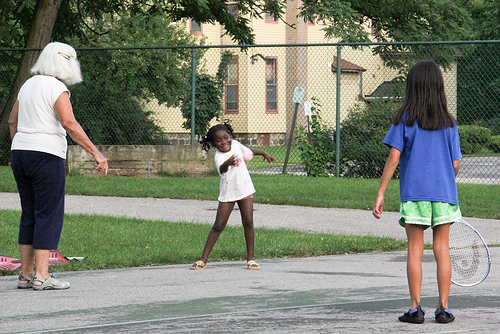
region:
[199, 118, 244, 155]
the head of the girl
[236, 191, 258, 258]
the leg of the girl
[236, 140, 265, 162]
the arm of the girl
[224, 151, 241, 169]
the hand of the girl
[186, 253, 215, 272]
the foot of the girl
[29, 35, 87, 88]
the head of the woman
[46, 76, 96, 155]
the arm of the woman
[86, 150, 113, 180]
the hand of the woman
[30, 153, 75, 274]
the leg of the woman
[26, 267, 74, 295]
the foot of the woman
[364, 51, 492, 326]
The closest girl has a tennis racket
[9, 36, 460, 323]
There are three people in the shot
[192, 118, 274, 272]
The middle girl has on a white shirt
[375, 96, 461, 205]
The girl on right has on a blue shirt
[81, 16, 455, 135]
The house is a light orange color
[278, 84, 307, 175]
The sign and post are bent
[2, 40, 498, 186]
The fence is chain link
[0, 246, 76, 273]
There is pink sports equipment in the grass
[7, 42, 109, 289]
The woman on left is elderly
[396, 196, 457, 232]
Person on right is wearing green shorts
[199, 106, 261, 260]
girl is playing on sidewalk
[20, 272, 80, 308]
lady has on grey shoes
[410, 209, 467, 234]
girl is wearing green shorts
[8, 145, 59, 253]
woman has black pants on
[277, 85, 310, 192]
the sign is crooked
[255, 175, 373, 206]
the grass behind the girl is green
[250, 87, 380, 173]
there is a fence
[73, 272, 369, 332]
sidewalk is gray in color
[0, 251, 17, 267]
pink equipment on ground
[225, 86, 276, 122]
building has two windows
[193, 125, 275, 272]
Girl in white shirt throwing ball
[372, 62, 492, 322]
Girl in blue holding tennis racket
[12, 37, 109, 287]
Lady with white hair wearing white shirt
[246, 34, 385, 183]
Grey chain linked fence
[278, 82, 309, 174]
White parking sign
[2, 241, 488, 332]
Grey asphalt courtyard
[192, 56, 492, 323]
Children playing outside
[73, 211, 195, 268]
Green mowed grass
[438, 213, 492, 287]
White and purple tennis racket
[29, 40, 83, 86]
Hair clip in white hair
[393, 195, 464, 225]
green and white shorts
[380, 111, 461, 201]
purple top on little girl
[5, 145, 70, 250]
black pants on lady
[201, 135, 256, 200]
white tee shirt on little girl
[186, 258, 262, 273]
white sandals on little girl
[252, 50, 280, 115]
front window of building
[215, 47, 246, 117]
side window of building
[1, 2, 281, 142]
tall tree on side of woman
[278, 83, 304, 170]
street sign in ground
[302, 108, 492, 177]
bushes in front of building